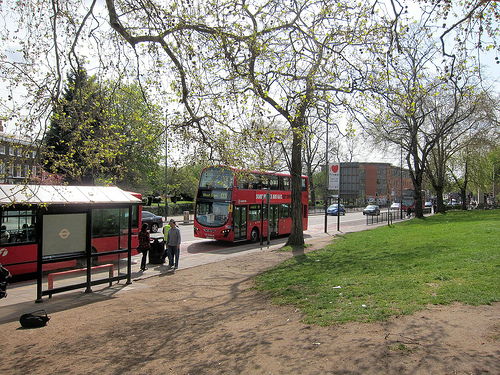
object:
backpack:
[13, 309, 59, 336]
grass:
[285, 255, 497, 322]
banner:
[327, 164, 342, 193]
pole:
[334, 164, 344, 234]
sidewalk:
[175, 229, 303, 254]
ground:
[21, 290, 474, 356]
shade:
[86, 316, 485, 374]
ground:
[212, 301, 280, 371]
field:
[0, 208, 500, 373]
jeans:
[159, 243, 204, 269]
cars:
[326, 199, 398, 214]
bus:
[0, 177, 153, 277]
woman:
[137, 222, 160, 274]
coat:
[138, 230, 155, 252]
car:
[359, 202, 384, 222]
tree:
[263, 78, 324, 252]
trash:
[330, 283, 343, 294]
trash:
[358, 297, 368, 309]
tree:
[410, 0, 443, 218]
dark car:
[134, 208, 166, 233]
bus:
[188, 156, 325, 247]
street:
[126, 195, 413, 246]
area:
[264, 209, 498, 312]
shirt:
[165, 227, 177, 245]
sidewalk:
[4, 242, 280, 265]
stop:
[2, 178, 146, 300]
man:
[165, 220, 183, 270]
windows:
[338, 163, 361, 195]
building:
[314, 160, 418, 207]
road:
[6, 204, 447, 267]